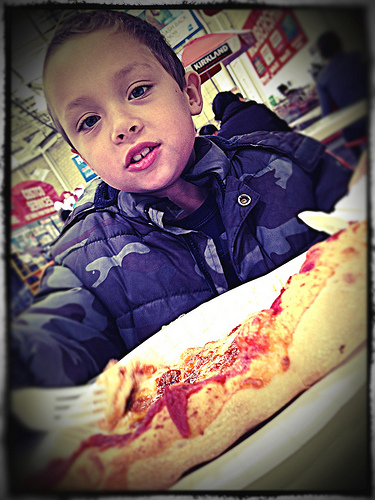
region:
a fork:
[15, 349, 133, 455]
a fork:
[33, 368, 169, 489]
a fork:
[68, 381, 118, 486]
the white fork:
[13, 385, 107, 422]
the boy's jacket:
[24, 125, 348, 366]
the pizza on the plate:
[61, 268, 374, 453]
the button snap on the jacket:
[235, 193, 250, 208]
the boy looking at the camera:
[26, 13, 257, 293]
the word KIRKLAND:
[191, 45, 232, 72]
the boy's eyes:
[65, 79, 151, 135]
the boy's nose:
[108, 103, 143, 143]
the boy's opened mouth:
[114, 139, 160, 171]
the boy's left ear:
[182, 69, 199, 114]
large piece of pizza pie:
[35, 223, 351, 470]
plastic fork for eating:
[4, 342, 148, 440]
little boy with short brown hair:
[44, 12, 225, 200]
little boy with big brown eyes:
[27, 47, 177, 148]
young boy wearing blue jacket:
[21, 87, 309, 351]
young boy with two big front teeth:
[56, 107, 204, 198]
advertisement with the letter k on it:
[166, 26, 260, 85]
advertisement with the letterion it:
[158, 34, 277, 92]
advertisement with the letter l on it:
[162, 22, 269, 88]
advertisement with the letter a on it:
[159, 23, 289, 103]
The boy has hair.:
[36, 7, 320, 275]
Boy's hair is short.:
[32, 10, 283, 242]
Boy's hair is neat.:
[29, 3, 289, 258]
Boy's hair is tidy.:
[35, 0, 221, 205]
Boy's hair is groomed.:
[25, 0, 275, 236]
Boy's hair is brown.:
[25, 2, 291, 258]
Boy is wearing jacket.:
[16, 6, 370, 389]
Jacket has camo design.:
[8, 10, 362, 381]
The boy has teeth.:
[31, 4, 293, 281]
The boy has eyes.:
[28, 2, 283, 270]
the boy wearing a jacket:
[22, 27, 347, 485]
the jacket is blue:
[31, 131, 373, 343]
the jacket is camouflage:
[40, 132, 372, 300]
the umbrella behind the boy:
[168, 33, 271, 86]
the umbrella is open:
[167, 26, 264, 92]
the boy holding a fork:
[35, 13, 325, 268]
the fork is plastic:
[3, 368, 142, 458]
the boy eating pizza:
[19, 19, 372, 355]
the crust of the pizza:
[74, 260, 367, 497]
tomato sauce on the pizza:
[85, 384, 201, 440]